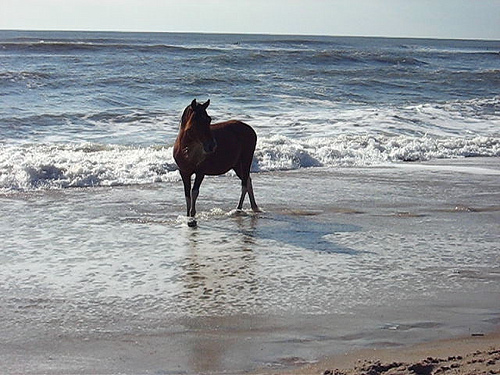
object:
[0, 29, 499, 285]
ocean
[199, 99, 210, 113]
ear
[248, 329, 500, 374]
traces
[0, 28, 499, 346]
seawater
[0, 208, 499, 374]
beach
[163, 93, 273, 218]
horse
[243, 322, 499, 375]
sand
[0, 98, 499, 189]
waves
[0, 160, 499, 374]
shore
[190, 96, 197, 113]
ear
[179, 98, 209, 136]
head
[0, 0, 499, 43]
sky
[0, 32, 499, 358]
water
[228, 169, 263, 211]
leg